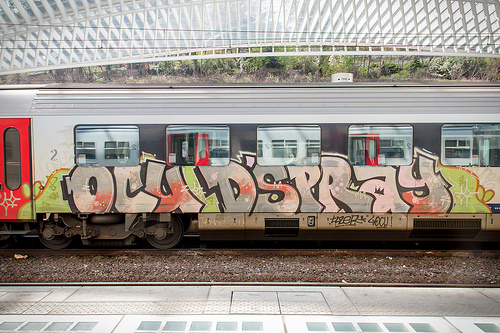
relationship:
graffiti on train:
[1, 152, 499, 226] [1, 84, 499, 245]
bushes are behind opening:
[398, 61, 492, 78] [147, 63, 493, 77]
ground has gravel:
[3, 251, 499, 281] [92, 254, 173, 276]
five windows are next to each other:
[68, 123, 499, 179] [78, 144, 488, 150]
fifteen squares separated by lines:
[3, 314, 499, 332] [107, 310, 132, 332]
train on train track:
[1, 84, 499, 245] [2, 243, 494, 258]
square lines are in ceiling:
[5, 10, 497, 68] [6, 1, 500, 72]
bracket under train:
[194, 212, 499, 242] [1, 84, 499, 245]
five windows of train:
[68, 123, 499, 179] [1, 84, 499, 245]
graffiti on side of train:
[1, 152, 499, 226] [1, 84, 499, 245]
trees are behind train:
[187, 63, 354, 74] [1, 84, 499, 245]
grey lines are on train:
[30, 89, 499, 117] [1, 84, 499, 245]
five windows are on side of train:
[68, 123, 499, 179] [1, 84, 499, 245]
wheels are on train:
[34, 209, 193, 252] [1, 84, 499, 245]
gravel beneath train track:
[92, 254, 173, 276] [2, 243, 494, 258]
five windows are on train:
[68, 123, 499, 179] [1, 84, 499, 245]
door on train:
[0, 107, 40, 220] [1, 84, 499, 245]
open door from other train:
[160, 128, 217, 169] [72, 127, 485, 165]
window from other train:
[265, 137, 304, 158] [72, 127, 485, 165]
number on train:
[50, 147, 64, 164] [1, 84, 499, 245]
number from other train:
[260, 138, 274, 154] [72, 127, 485, 165]